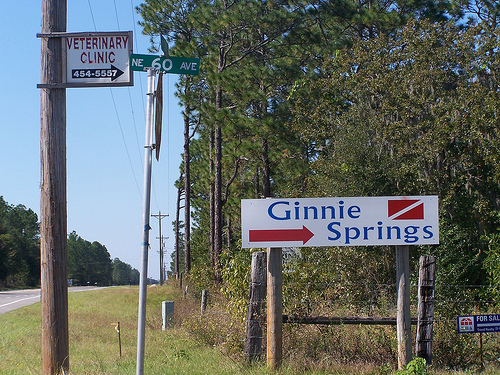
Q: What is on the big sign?
A: Ginnie Springs.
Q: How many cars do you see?
A: Zero.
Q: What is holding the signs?
A: Wood poles.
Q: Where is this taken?
A: The side of the road.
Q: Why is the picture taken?
A: To show signs.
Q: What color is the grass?
A: Green and brown.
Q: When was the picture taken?
A: Daytime.